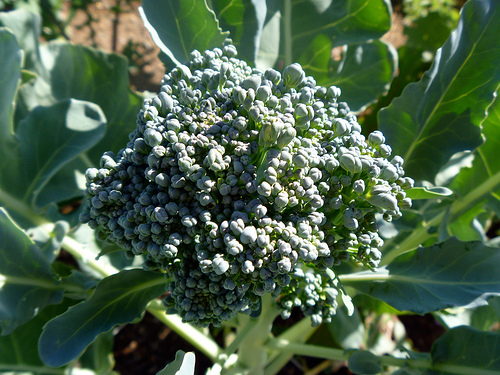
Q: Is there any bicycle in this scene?
A: No, there are no bicycles.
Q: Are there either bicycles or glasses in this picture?
A: No, there are no bicycles or glasses.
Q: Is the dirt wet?
A: Yes, the dirt is wet.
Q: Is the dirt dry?
A: No, the dirt is wet.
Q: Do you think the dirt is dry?
A: No, the dirt is wet.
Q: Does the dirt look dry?
A: No, the dirt is wet.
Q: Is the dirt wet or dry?
A: The dirt is wet.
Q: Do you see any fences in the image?
A: No, there are no fences.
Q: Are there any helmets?
A: No, there are no helmets.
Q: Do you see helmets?
A: No, there are no helmets.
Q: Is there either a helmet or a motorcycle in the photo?
A: No, there are no helmets or motorcycles.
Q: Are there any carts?
A: No, there are no carts.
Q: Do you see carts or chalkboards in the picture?
A: No, there are no carts or chalkboards.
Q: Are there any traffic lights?
A: No, there are no traffic lights.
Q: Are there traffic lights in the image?
A: No, there are no traffic lights.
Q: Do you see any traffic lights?
A: No, there are no traffic lights.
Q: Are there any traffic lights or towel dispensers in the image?
A: No, there are no traffic lights or towel dispensers.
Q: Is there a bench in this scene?
A: No, there are no benches.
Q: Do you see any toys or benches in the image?
A: No, there are no benches or toys.